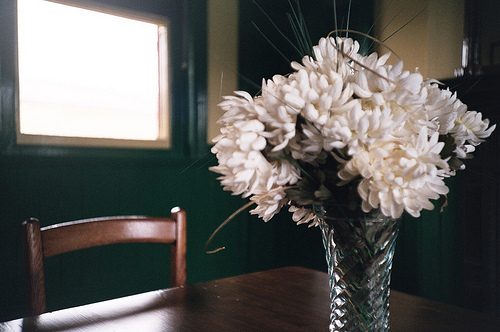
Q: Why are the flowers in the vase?
A: To hold them together.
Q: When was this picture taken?
A: During the day.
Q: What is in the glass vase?
A: Flowers.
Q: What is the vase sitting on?
A: A table.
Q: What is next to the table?
A: A chair.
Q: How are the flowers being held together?
A: With a vase.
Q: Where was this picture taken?
A: In dinning room.